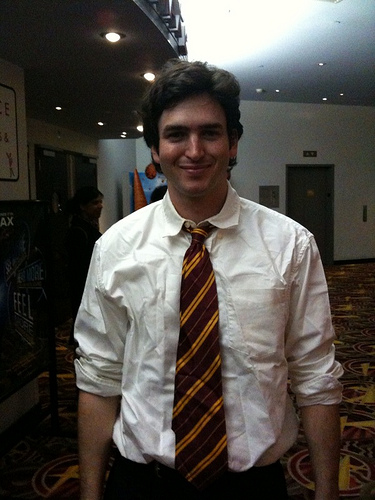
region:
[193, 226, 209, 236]
yellow strip on tie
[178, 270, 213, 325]
yellow strip on tie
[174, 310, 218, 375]
yellow strip on tie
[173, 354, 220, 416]
yellow strip on tie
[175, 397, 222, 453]
yellow strip on tie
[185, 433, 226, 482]
yellow strip on tie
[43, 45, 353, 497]
this is a man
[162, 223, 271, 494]
this is a tie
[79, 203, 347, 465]
the man is in a white shirt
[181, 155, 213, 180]
the mouth of a man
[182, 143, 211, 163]
the nose of a man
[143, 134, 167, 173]
the ear of a man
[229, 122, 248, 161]
the ear of a man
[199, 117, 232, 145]
the eye of a man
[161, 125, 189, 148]
the eye of a man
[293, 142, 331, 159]
black sign over door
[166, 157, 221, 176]
grin on man's face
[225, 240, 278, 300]
wrinkles on man's white shirt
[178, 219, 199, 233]
small white button on shirt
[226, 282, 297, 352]
large white pocket on the shirt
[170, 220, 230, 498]
a long tie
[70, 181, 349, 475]
a long sleeve shirt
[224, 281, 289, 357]
a pocket on shirt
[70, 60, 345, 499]
a guy standing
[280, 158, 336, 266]
a door entrance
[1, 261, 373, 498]
the rug of many colors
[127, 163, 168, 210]
a poster with ball on it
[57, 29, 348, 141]
the lights in ceiling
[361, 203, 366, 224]
panel to elevator on wall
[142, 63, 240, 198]
head of a smiling man with dark hair posing for a photo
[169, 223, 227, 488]
maroon tie with diagonal yellow stripes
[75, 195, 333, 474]
rumpled white button down shirt with rolled up long sleeves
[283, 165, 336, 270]
grey elevator door in background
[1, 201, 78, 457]
black metal stand for advertising posters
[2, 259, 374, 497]
carpeting with large bold designs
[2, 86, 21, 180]
black and white sign on which the letter E can be seen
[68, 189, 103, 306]
dark haired woman in front of closed double doors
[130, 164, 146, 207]
orange cone on large 3d advertisment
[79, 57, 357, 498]
this is a person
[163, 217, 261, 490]
this is a stripped tie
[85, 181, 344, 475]
the man is in a white shirt